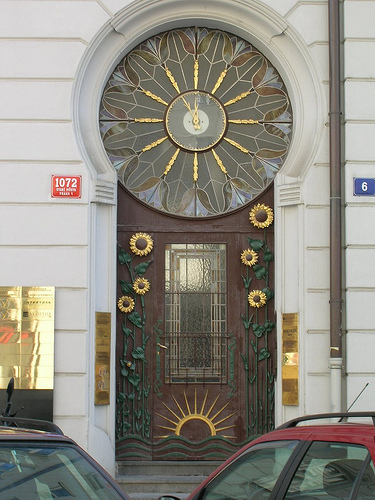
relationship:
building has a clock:
[2, 5, 373, 497] [100, 26, 291, 217]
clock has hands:
[100, 26, 291, 217] [179, 91, 203, 129]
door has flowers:
[127, 224, 268, 463] [235, 244, 264, 324]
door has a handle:
[127, 224, 268, 463] [154, 340, 168, 352]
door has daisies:
[127, 224, 268, 463] [115, 231, 153, 314]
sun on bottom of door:
[146, 389, 245, 443] [127, 224, 268, 463]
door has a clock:
[127, 224, 268, 463] [100, 26, 291, 217]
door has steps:
[127, 224, 268, 463] [113, 460, 276, 496]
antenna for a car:
[333, 378, 374, 425] [158, 410, 373, 498]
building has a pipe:
[2, 5, 373, 497] [325, 4, 352, 424]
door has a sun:
[127, 224, 268, 463] [146, 389, 245, 443]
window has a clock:
[96, 26, 298, 221] [100, 26, 291, 217]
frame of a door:
[82, 179, 314, 485] [127, 224, 268, 463]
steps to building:
[113, 460, 276, 496] [2, 5, 373, 497]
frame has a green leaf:
[82, 179, 314, 485] [247, 326, 277, 399]